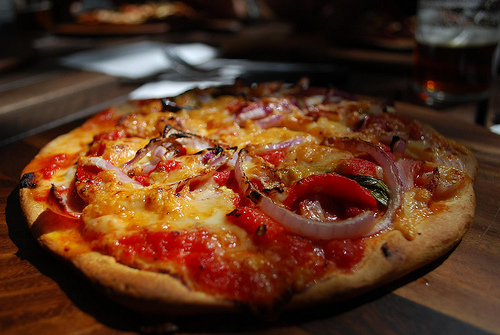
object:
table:
[1, 73, 498, 332]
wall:
[378, 157, 403, 192]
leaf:
[352, 174, 392, 206]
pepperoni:
[229, 156, 395, 268]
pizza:
[20, 77, 478, 315]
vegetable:
[353, 175, 392, 206]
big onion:
[96, 124, 407, 240]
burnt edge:
[137, 123, 224, 154]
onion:
[85, 124, 237, 192]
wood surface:
[1, 254, 498, 331]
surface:
[1, 58, 497, 328]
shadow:
[3, 181, 463, 335]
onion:
[234, 132, 404, 239]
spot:
[19, 171, 39, 188]